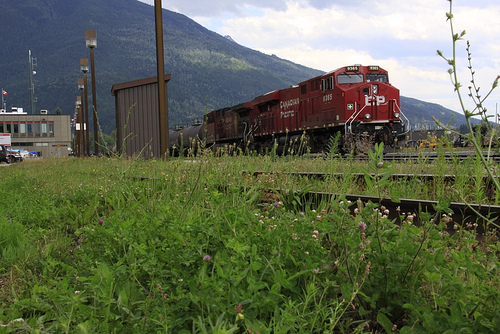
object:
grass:
[0, 142, 500, 333]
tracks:
[72, 171, 500, 224]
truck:
[171, 122, 208, 155]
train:
[168, 63, 404, 151]